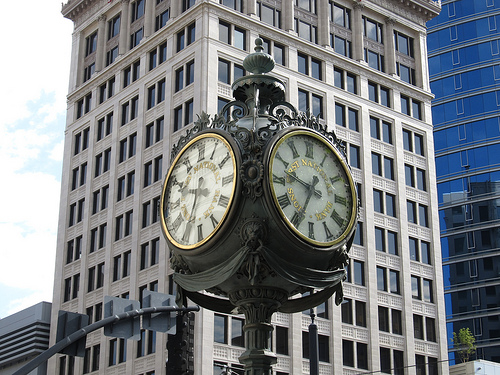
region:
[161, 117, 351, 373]
A clock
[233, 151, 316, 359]
A clock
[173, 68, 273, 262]
A clock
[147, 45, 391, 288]
clocks with the Roman numeral I on it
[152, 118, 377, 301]
clocks with the Roman numeral II on it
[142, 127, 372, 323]
clocks with the Roman numeral III on it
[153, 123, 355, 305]
clocks with the Roman numeral IV on it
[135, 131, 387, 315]
clocks with the Roman numeral V on it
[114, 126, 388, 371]
clocks with the Roman numeral VI on it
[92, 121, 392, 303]
clocks with the Roman numeral VII on it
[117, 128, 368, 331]
clocks with the Roman numeral VIII on it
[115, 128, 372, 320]
clocks with the Roman numeral IX on it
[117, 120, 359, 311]
clocks with the Roman numeral X on it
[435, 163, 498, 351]
Reflection of building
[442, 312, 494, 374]
Tree on rooftop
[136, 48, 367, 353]
Big Clock outside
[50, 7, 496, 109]
Tall Buildings in a big city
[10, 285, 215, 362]
Street Signs in a big city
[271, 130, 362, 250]
Face of outside Clock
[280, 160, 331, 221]
Clock Hands showing min and hour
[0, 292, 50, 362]
Building Rooftop in the city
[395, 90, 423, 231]
Window on a large building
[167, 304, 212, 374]
Stop Light on a pole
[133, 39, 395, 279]
A clock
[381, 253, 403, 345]
A building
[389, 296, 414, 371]
A building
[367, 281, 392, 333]
A building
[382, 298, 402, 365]
A building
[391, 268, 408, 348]
A building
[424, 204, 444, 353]
A building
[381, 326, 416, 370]
A building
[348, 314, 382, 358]
A building